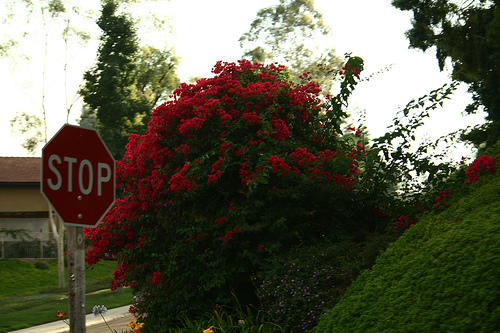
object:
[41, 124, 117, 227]
stop sign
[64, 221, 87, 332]
post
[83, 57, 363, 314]
plant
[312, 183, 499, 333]
hill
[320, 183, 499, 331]
ground cover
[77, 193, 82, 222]
bolts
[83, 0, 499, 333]
plants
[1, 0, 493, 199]
sky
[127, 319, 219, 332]
flowers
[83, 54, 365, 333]
bush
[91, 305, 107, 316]
flower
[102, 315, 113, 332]
stem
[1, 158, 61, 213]
roof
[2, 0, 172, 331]
background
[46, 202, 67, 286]
trunk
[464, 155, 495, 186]
bush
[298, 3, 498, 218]
background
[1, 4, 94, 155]
branches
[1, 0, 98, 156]
tree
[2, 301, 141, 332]
sidewalk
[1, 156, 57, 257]
building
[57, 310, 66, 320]
flower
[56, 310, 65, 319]
petals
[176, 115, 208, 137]
flowers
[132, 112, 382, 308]
leaves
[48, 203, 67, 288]
tree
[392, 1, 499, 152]
tree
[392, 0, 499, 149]
leaves